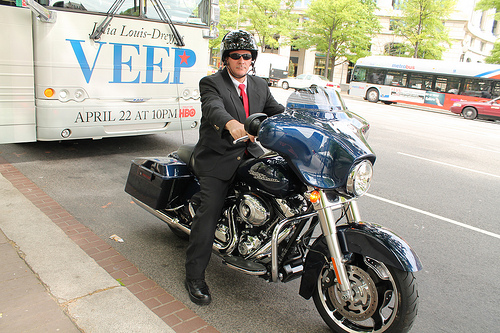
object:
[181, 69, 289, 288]
suit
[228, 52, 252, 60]
glasses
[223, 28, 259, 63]
helmet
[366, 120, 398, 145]
ground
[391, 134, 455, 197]
ground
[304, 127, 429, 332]
front motorcycle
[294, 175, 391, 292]
motorcycle fork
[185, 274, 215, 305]
dress shoe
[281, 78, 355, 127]
winshield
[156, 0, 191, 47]
windshield wipers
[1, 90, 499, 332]
pavement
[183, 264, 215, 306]
black shoe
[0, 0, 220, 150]
bus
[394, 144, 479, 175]
line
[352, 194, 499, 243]
line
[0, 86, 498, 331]
street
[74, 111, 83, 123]
letter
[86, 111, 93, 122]
letter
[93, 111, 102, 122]
letter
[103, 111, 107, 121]
letter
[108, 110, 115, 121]
letter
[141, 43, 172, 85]
letter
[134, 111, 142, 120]
letter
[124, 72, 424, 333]
motorcycle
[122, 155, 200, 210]
storage bin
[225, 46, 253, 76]
face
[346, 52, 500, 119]
bus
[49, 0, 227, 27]
windshield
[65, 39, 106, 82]
letter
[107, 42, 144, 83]
letter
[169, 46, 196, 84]
letter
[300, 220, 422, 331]
wheel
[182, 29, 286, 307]
man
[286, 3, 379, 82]
tree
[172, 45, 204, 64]
star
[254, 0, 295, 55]
trees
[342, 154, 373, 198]
headlight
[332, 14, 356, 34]
leaves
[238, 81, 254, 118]
tie